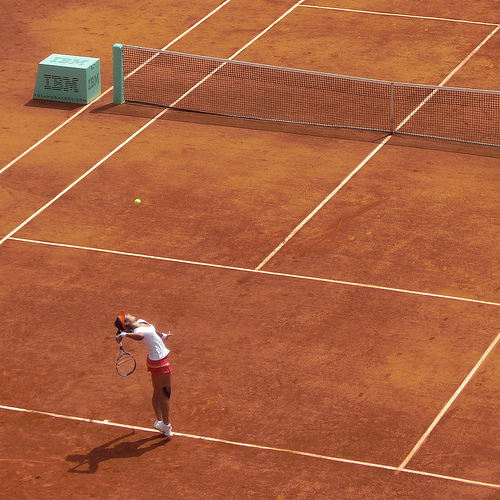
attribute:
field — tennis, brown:
[3, 2, 496, 497]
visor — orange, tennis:
[115, 310, 127, 331]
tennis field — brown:
[2, 0, 497, 499]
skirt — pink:
[141, 357, 176, 377]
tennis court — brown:
[0, 9, 478, 491]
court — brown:
[1, 0, 498, 497]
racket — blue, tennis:
[85, 314, 153, 380]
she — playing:
[101, 307, 195, 445]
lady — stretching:
[109, 315, 191, 440]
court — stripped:
[157, 200, 374, 325]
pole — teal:
[104, 42, 133, 112]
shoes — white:
[148, 421, 177, 438]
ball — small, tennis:
[134, 196, 142, 208]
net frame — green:
[112, 45, 129, 107]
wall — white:
[144, 137, 227, 160]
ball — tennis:
[126, 188, 152, 212]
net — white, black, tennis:
[271, 64, 421, 164]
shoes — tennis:
[152, 417, 177, 439]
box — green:
[35, 51, 109, 109]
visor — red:
[110, 311, 128, 329]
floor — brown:
[240, 308, 420, 418]